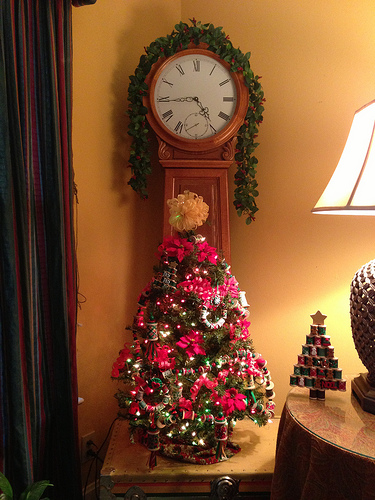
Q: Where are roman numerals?
A: On the clock.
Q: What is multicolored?
A: The curtains.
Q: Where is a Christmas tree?
A: On a table.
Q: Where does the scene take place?
A: In a house.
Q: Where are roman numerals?
A: On the clock.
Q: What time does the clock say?
A: 4:45.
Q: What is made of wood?
A: Base of clock.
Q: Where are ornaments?
A: On Christmas tree.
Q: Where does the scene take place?
A: In a living room.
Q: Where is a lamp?
A: On round table.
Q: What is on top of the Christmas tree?
A: Yellow bow.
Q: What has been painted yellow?
A: The walls.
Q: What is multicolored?
A: The curtains.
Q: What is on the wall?
A: Clock.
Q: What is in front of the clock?
A: A tree.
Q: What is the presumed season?
A: Winter.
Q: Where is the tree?
A: In front of the clock.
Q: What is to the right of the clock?
A: The lamp.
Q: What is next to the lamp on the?
A: A miniature tree.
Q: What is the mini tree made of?
A: Spools.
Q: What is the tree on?
A: The table.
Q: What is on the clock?
A: Ivy.